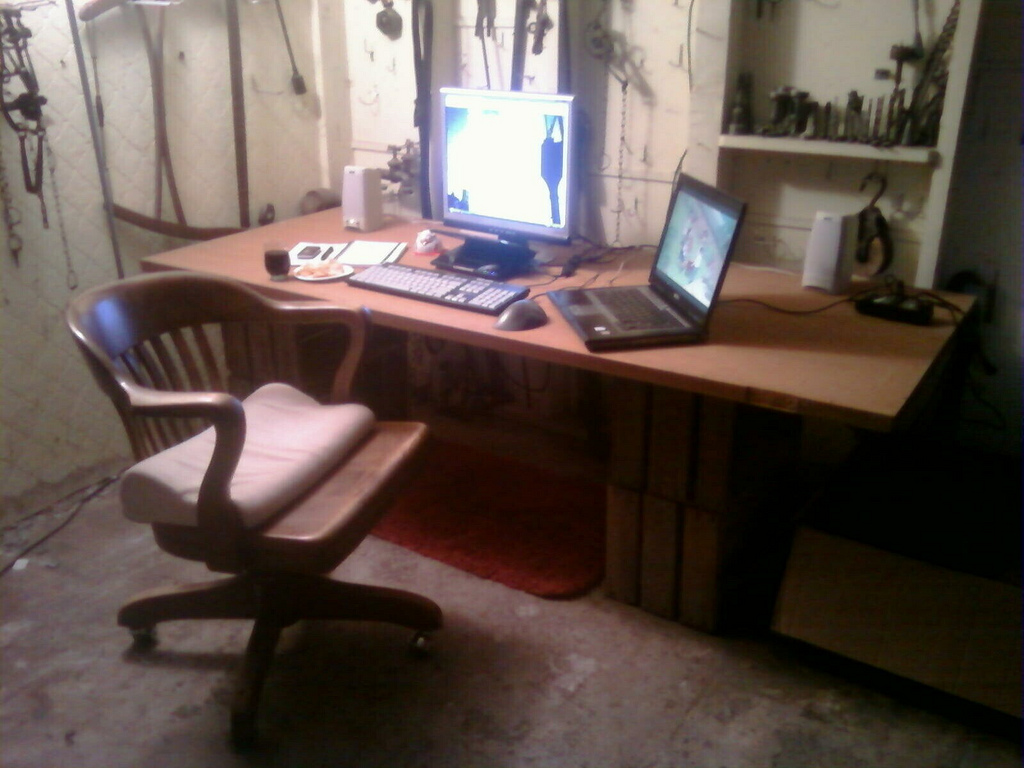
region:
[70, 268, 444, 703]
a chair that is brown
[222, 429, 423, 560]
the seat of a chair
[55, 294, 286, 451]
the back of a chair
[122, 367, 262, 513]
the right arm of a chair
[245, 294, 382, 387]
the left arm of a chair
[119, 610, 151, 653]
the wheel of a chair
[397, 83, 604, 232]
a small grey computer screen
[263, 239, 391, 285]
a bunch of paper on a desk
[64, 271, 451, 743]
Brown wooden chair with wheels.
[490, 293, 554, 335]
Grey computer mouse on desk.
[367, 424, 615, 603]
Square red rug under the desk.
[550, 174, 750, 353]
Black laptop on top of desk.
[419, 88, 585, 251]
Grey computer monitor on desk.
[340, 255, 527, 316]
Black computer keyboard with white keys.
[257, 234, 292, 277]
Glass with dark drink in it.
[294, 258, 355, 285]
Small white plate with food on it.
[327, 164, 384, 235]
Grey speaker that has a dial.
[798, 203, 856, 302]
Grey speaker that does not have a dial.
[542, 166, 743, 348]
Laptop computer sitting open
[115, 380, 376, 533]
flat white seat cushion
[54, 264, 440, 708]
Brown wooden rolling chair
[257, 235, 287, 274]
Beverage glass sitting on table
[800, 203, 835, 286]
Cream colored computer speaker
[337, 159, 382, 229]
Cream colored computer speaker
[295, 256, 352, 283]
plate full of food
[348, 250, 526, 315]
Blackand white keyboard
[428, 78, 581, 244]
Large operating computer screen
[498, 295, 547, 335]
Small black computer mouse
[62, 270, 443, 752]
a wooden swiveling chair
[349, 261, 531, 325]
a black keyboard in front of a monitor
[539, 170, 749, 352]
a black laptop on a desk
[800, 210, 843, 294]
a white speaker sitting on a desk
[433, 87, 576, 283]
a monitor on a black stand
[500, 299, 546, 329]
a wired black mouse on a desk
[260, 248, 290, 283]
a small cup of red wine on a desk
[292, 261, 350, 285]
a small white plate on a desk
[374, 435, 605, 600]
a red rug underneath a desk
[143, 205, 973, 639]
a wooden desk in front of a chair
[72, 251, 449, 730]
rolling chair next to the desk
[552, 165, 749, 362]
open black laptop on the desk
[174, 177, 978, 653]
desk the laptop is on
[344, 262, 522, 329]
gray and white keyboard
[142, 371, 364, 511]
white cushion in the chair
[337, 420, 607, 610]
red rug on the floor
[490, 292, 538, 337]
silver mouse on the desk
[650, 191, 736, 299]
screen of the laptop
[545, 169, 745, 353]
open black laptop computer on desk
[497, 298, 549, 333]
large silver wireless mouse on desk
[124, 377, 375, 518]
curved white seat cushion on wooden office chair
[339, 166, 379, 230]
white computer speaker on wooden desk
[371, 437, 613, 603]
fluffy red rug under wood desk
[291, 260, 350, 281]
small round white plate on wood desk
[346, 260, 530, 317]
black computer keyboard with small gray computer keys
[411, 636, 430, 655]
small black wheel in bronze casing on office chair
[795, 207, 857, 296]
right square computer speaker on desk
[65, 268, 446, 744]
the cushion on the chair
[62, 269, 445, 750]
the office chair is made of wood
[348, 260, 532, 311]
the keyboard is black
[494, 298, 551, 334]
the mouse is black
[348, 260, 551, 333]
the mouse next to the keyboard